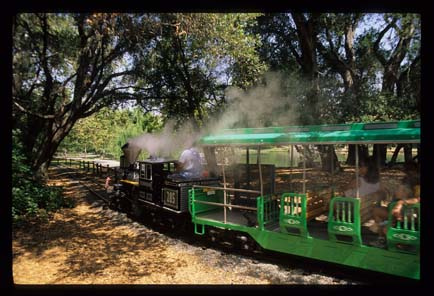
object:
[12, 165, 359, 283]
dirt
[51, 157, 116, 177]
fence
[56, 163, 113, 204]
train track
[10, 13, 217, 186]
tree